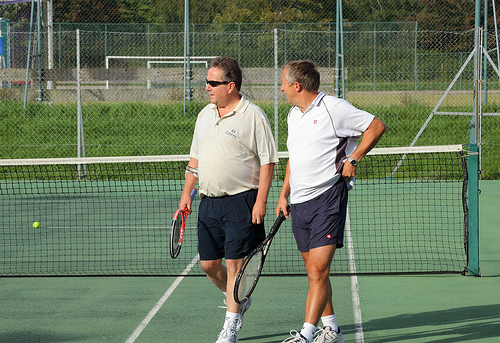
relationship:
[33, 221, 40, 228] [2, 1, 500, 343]
tennis ball in court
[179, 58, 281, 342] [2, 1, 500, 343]
man standing in court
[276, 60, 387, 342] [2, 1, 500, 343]
man standing in court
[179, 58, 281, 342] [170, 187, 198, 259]
man holding tennis racket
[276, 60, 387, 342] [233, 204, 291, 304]
man holding tennis racket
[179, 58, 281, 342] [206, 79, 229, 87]
man wearing sunglasses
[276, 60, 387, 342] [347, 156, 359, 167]
man wearing wrist watch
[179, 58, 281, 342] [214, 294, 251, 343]
man wearing shoes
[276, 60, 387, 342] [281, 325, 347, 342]
man wearing shoes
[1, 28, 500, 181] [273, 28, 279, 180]
fence on post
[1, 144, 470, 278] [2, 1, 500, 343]
tennis net in court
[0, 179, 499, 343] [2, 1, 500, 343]
ground of court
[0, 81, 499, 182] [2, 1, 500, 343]
grass behind court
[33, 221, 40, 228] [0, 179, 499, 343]
tennis ball on ground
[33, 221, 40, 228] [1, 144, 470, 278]
tennis ball behind tennis net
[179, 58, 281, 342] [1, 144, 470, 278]
man in front of tennis net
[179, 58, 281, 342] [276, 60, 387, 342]
man next to man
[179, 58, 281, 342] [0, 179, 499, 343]
man standing on ground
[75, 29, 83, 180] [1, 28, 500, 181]
pole on fence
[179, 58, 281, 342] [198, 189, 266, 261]
man wearing shorts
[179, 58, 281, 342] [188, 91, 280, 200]
man wearing polo shirt